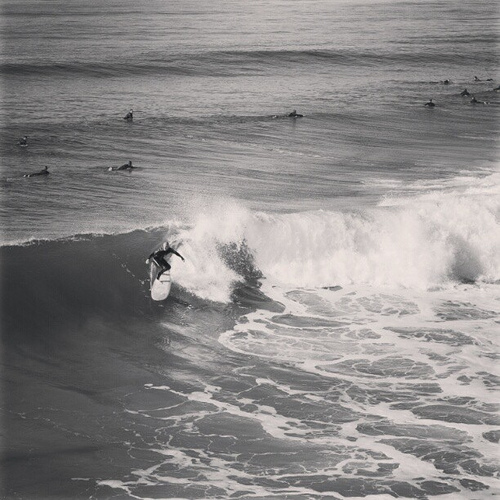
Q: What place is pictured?
A: It is a sea.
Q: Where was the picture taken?
A: It was taken at the sea.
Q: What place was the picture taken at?
A: It was taken at the sea.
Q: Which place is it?
A: It is a sea.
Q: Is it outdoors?
A: Yes, it is outdoors.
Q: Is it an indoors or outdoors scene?
A: It is outdoors.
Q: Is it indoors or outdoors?
A: It is outdoors.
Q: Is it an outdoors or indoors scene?
A: It is outdoors.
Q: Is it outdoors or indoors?
A: It is outdoors.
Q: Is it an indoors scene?
A: No, it is outdoors.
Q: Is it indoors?
A: No, it is outdoors.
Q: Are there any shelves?
A: No, there are no shelves.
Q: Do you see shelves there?
A: No, there are no shelves.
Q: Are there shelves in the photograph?
A: No, there are no shelves.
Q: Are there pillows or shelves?
A: No, there are no shelves or pillows.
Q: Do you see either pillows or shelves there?
A: No, there are no shelves or pillows.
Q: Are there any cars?
A: No, there are no cars.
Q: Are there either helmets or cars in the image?
A: No, there are no cars or helmets.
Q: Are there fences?
A: No, there are no fences.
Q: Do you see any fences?
A: No, there are no fences.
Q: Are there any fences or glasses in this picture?
A: No, there are no fences or glasses.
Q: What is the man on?
A: The man is on the surfboard.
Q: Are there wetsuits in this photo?
A: Yes, there is a wetsuit.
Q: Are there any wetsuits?
A: Yes, there is a wetsuit.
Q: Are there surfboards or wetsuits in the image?
A: Yes, there is a wetsuit.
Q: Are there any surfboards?
A: Yes, there is a surfboard.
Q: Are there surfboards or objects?
A: Yes, there is a surfboard.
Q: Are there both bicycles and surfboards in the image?
A: No, there is a surfboard but no bicycles.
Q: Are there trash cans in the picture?
A: No, there are no trash cans.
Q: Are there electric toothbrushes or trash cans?
A: No, there are no trash cans or electric toothbrushes.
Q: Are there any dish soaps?
A: No, there are no dish soaps.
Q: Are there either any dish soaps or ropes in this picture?
A: No, there are no dish soaps or ropes.